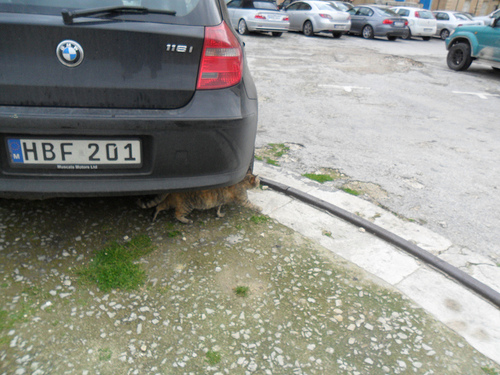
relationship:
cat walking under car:
[133, 171, 260, 223] [1, 0, 259, 199]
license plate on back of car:
[1, 125, 155, 174] [1, 0, 259, 199]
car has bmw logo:
[1, 0, 259, 199] [52, 34, 93, 71]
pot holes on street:
[343, 169, 402, 210] [268, 44, 496, 266]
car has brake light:
[1, 0, 259, 199] [195, 15, 246, 100]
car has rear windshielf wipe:
[1, 0, 259, 199] [56, 6, 191, 36]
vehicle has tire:
[220, 2, 295, 46] [234, 14, 250, 38]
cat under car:
[133, 171, 260, 223] [1, 0, 259, 199]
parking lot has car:
[181, 2, 499, 323] [286, 1, 355, 45]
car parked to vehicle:
[286, 1, 355, 45] [220, 2, 295, 46]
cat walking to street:
[133, 171, 260, 223] [268, 44, 496, 266]